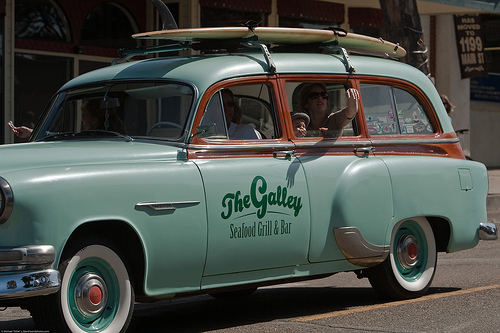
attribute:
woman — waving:
[297, 79, 359, 135]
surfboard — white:
[133, 21, 407, 67]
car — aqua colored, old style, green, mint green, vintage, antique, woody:
[1, 63, 499, 333]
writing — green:
[220, 178, 301, 247]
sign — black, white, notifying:
[455, 16, 484, 78]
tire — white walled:
[61, 242, 136, 333]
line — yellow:
[298, 273, 495, 331]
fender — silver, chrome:
[336, 231, 386, 269]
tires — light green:
[40, 214, 446, 329]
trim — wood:
[183, 75, 463, 159]